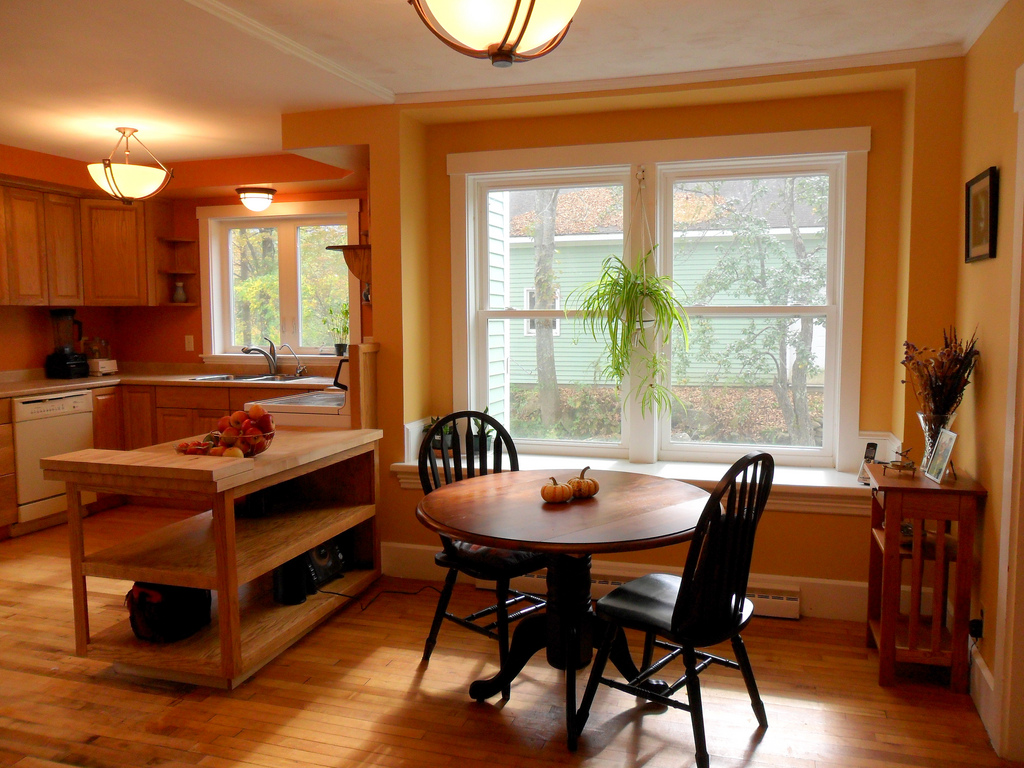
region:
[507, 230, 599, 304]
window on the building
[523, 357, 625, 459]
window on the building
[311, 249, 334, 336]
window on the building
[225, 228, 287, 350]
window on the building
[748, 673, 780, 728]
leg of the chair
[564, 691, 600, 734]
leg of the chair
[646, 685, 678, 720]
leg of the chair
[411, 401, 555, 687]
Black chair in front of the table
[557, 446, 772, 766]
Black chair in front of the table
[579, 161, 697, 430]
Green plant hung from the wall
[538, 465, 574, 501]
Small pumpkin sitting on the table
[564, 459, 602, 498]
Small pumpkin sitting on the table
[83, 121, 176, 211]
Light is hanging from the ceiling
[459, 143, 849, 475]
Large window next to the table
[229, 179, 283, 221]
Lit light by the window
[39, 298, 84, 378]
Black bender sitting on the counter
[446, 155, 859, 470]
Large window in kitchen.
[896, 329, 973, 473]
Foliage in glass vase.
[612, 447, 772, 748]
Black chairs in kitchen.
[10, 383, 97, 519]
White built-in dishwasher.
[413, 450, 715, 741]
Small brown breakfast table.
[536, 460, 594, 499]
Decorative pumpkins sitting on table.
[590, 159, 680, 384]
Hanging potted indoor plant.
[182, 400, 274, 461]
Decorative gourds on counter.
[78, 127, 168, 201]
Hanging light in kitchen.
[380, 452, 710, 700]
small and round table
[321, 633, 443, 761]
floor is light brown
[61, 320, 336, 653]
counter is light brown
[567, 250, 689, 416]
tall and green plant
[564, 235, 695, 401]
plant has thin leaves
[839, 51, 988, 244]
brown wall around window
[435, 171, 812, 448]
white frame on window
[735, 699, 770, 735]
leg of the furniture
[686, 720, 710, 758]
leg of the furniture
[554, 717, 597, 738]
leg of the furniture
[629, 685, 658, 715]
leg of the furniture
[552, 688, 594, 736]
leg of the furniture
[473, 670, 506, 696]
leg of the furniture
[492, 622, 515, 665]
leg of the furniture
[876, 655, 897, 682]
leg of the furniture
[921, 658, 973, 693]
leg of the furniture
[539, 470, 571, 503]
small orange pumpkin on round wooden table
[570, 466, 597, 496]
small orange pumpkin on round wooden table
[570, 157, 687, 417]
green plant hangs in white basket near double window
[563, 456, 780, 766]
black wooden chair pulled under wooden table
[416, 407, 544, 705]
black wooden chair pulled under wooden table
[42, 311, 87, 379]
bulky black blender on kitchen counter top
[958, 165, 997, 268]
black framed art hangs on right wall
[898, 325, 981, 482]
vase of dark purple flowers on wooden shelf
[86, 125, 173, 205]
domed overhead light with bronze hardware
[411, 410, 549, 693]
the chair is black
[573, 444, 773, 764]
the chair is black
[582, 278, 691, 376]
a plant hanging on the wall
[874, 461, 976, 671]
a small wooden shelf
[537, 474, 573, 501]
a pumpkin on the table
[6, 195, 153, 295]
wooden cabinets in the kitchen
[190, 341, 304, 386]
the sink in the kitchen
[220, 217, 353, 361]
a window above the sink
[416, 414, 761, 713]
a round table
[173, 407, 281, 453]
a bowl of fruit